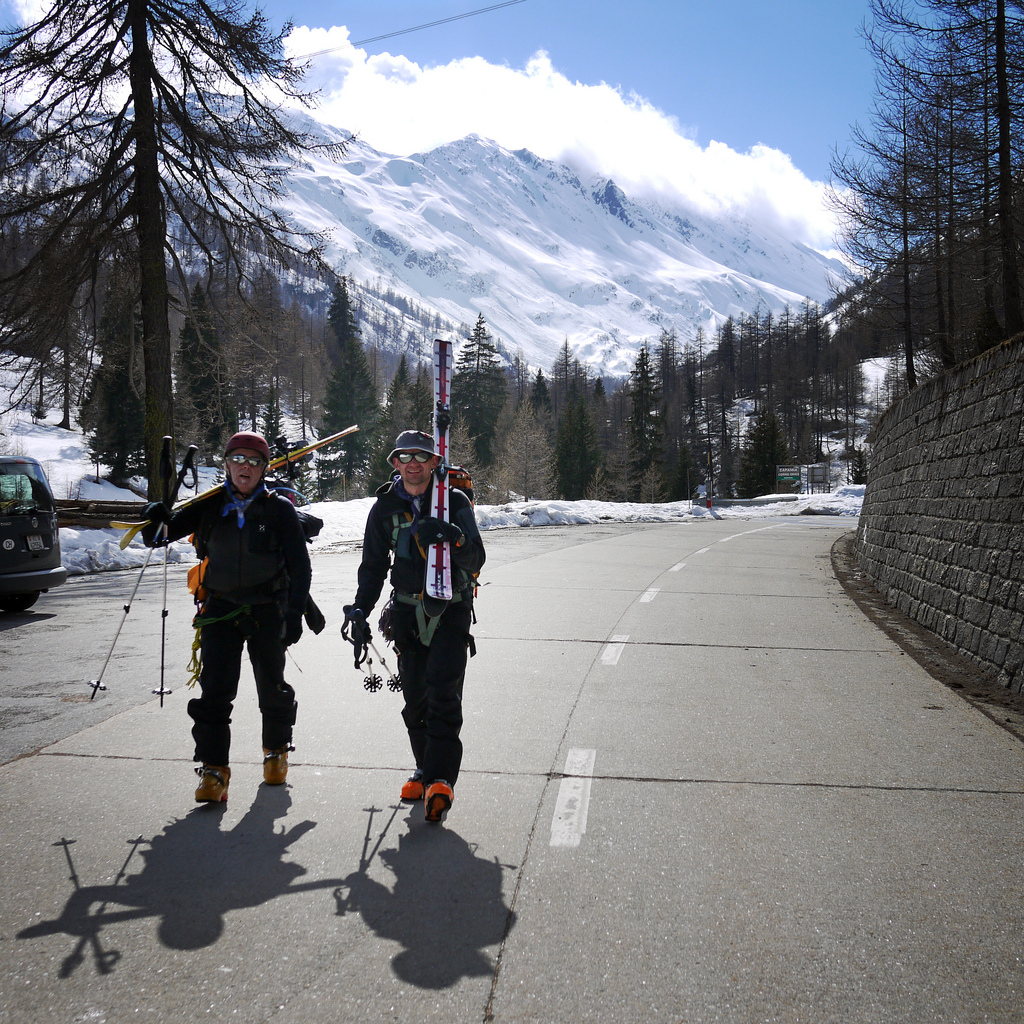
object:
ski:
[425, 336, 452, 601]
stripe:
[599, 633, 627, 665]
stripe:
[666, 559, 686, 572]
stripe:
[718, 520, 794, 544]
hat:
[388, 430, 445, 469]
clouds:
[0, 0, 1024, 381]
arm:
[417, 487, 485, 574]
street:
[0, 515, 1024, 1022]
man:
[340, 430, 485, 822]